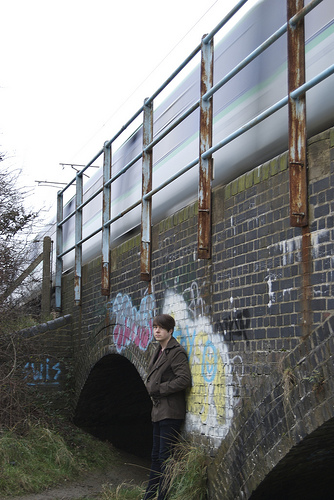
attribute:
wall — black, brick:
[34, 132, 332, 488]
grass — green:
[0, 380, 117, 494]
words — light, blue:
[22, 356, 61, 385]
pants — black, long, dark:
[142, 417, 182, 497]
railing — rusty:
[52, 12, 317, 329]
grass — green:
[10, 428, 64, 472]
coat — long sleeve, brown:
[149, 341, 190, 419]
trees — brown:
[0, 142, 52, 435]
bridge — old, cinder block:
[9, 0, 331, 496]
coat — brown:
[141, 336, 195, 421]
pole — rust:
[284, 0, 311, 230]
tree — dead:
[0, 143, 42, 431]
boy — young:
[141, 313, 190, 498]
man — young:
[138, 310, 192, 497]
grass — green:
[1, 399, 205, 498]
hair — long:
[148, 313, 176, 331]